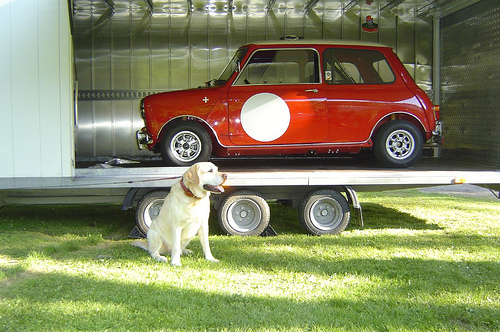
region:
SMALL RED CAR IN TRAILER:
[114, 18, 482, 163]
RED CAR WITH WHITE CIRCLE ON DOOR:
[108, 27, 437, 183]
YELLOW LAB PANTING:
[105, 132, 239, 283]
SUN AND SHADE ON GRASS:
[33, 194, 472, 330]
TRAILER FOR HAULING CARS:
[21, 8, 484, 232]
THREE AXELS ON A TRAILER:
[102, 104, 369, 251]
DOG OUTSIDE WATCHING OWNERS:
[91, 154, 283, 295]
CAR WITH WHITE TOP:
[117, 20, 476, 221]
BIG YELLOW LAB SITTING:
[101, 127, 306, 275]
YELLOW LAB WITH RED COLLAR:
[103, 113, 297, 267]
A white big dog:
[147, 167, 228, 284]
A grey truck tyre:
[294, 183, 361, 241]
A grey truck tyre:
[217, 185, 267, 242]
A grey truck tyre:
[135, 188, 172, 239]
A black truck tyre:
[371, 125, 421, 165]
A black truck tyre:
[164, 127, 218, 161]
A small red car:
[125, 45, 435, 156]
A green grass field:
[382, 215, 477, 326]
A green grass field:
[230, 253, 330, 330]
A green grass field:
[25, 234, 176, 329]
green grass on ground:
[420, 226, 443, 258]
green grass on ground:
[127, 236, 159, 276]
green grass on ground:
[167, 277, 227, 327]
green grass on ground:
[85, 290, 100, 296]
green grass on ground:
[55, 275, 125, 320]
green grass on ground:
[105, 241, 190, 306]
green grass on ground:
[400, 215, 480, 280]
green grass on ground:
[287, 282, 344, 317]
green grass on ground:
[11, 270, 56, 310]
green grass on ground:
[30, 195, 68, 257]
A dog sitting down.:
[129, 162, 227, 262]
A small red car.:
[140, 40, 441, 162]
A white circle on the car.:
[237, 90, 291, 141]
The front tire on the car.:
[160, 117, 214, 166]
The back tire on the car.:
[372, 118, 424, 167]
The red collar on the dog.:
[177, 176, 202, 206]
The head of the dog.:
[184, 161, 226, 196]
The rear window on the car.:
[322, 45, 395, 87]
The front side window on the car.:
[232, 46, 321, 89]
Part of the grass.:
[358, 310, 439, 323]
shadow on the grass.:
[137, 309, 169, 324]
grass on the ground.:
[244, 278, 295, 281]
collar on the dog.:
[179, 178, 199, 200]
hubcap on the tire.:
[230, 205, 257, 225]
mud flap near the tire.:
[350, 190, 365, 225]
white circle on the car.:
[257, 101, 278, 125]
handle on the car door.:
[299, 86, 319, 94]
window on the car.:
[255, 61, 304, 76]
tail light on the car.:
[431, 102, 448, 128]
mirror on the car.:
[231, 60, 241, 79]